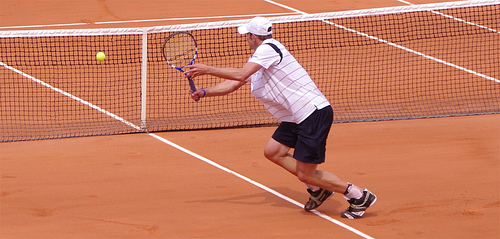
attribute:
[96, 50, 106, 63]
tennis ball — flying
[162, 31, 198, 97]
tennis racket — blue, white, black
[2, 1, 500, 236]
tennis court — brown, white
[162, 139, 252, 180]
painted lines — white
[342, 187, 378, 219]
tennis shoes — black, white